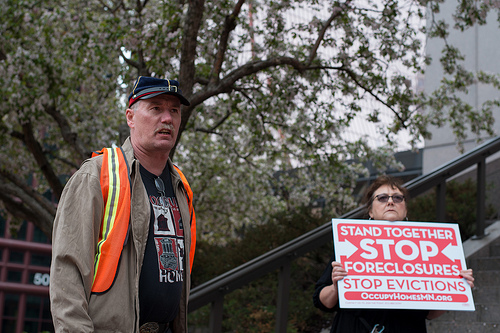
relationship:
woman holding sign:
[359, 177, 414, 220] [329, 221, 477, 312]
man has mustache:
[22, 74, 212, 331] [157, 119, 175, 136]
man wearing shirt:
[22, 74, 212, 331] [132, 162, 191, 328]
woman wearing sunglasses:
[359, 177, 414, 220] [375, 193, 411, 205]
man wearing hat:
[22, 74, 212, 331] [120, 76, 196, 104]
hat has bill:
[120, 76, 196, 104] [140, 89, 191, 107]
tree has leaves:
[23, 12, 364, 68] [48, 22, 104, 73]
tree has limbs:
[23, 12, 364, 68] [181, 6, 293, 81]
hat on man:
[120, 76, 196, 104] [22, 74, 212, 331]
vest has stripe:
[92, 152, 204, 285] [102, 150, 129, 224]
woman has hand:
[359, 177, 414, 220] [329, 261, 347, 282]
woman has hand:
[359, 177, 414, 220] [459, 263, 483, 291]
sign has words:
[329, 221, 477, 312] [342, 223, 467, 300]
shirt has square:
[132, 162, 191, 328] [152, 200, 173, 239]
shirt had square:
[132, 162, 191, 328] [150, 237, 178, 279]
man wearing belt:
[22, 74, 212, 331] [134, 316, 177, 332]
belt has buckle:
[134, 316, 177, 332] [135, 321, 163, 332]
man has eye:
[22, 74, 212, 331] [148, 105, 164, 113]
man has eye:
[22, 74, 212, 331] [169, 107, 180, 116]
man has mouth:
[22, 74, 212, 331] [154, 128, 180, 139]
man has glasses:
[22, 74, 212, 331] [150, 173, 175, 212]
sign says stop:
[329, 221, 477, 312] [361, 237, 447, 264]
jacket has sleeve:
[83, 150, 209, 291] [42, 170, 118, 331]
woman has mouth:
[359, 177, 414, 220] [381, 206, 401, 217]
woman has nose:
[359, 177, 414, 220] [385, 195, 396, 208]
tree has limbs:
[23, 12, 364, 68] [5, 101, 72, 188]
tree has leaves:
[23, 12, 364, 68] [150, 14, 189, 40]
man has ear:
[22, 74, 212, 331] [125, 105, 141, 128]